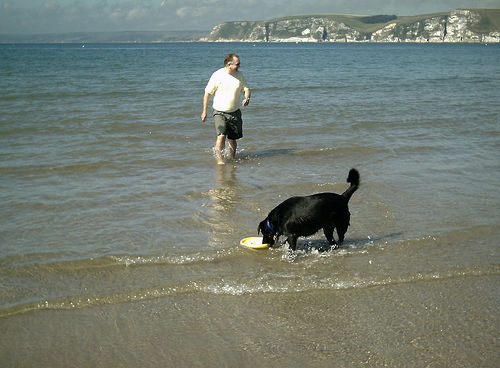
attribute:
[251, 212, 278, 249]
head — black  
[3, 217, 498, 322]
waves — small  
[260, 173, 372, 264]
dog — black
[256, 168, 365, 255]
dog — black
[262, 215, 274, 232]
collar — blue 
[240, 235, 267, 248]
disc — yellow 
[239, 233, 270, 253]
dish — edge 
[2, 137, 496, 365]
shore — edge 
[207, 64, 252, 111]
shirt — short, sleeved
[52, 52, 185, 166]
wall — calm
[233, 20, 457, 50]
rock cliff — face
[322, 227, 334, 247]
legs — black  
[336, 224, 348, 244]
legs — black  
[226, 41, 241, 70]
hair — brown  